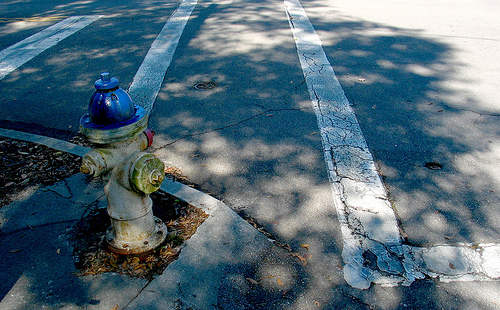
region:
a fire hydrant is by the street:
[74, 65, 171, 257]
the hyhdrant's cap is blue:
[76, 70, 147, 132]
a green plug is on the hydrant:
[129, 150, 167, 198]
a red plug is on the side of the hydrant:
[136, 126, 156, 151]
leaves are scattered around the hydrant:
[4, 131, 264, 308]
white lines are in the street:
[137, 6, 429, 284]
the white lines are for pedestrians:
[138, 7, 405, 293]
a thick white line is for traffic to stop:
[6, 7, 113, 134]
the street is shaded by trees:
[14, 8, 496, 284]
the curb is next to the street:
[7, 125, 279, 308]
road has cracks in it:
[180, 70, 320, 197]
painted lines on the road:
[81, 20, 413, 90]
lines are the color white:
[271, 50, 415, 281]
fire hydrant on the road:
[55, 75, 250, 305]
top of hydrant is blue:
[77, 40, 146, 143]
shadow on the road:
[13, 4, 472, 204]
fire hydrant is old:
[64, 57, 207, 232]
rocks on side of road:
[20, 127, 125, 251]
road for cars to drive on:
[34, 6, 470, 296]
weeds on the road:
[238, 205, 341, 300]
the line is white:
[377, 205, 390, 237]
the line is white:
[371, 220, 381, 229]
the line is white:
[376, 217, 385, 227]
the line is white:
[357, 203, 367, 242]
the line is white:
[372, 223, 384, 231]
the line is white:
[385, 201, 390, 231]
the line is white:
[363, 228, 376, 251]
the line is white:
[376, 223, 388, 254]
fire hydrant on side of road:
[68, 65, 180, 258]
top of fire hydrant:
[72, 73, 144, 144]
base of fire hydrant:
[101, 222, 168, 253]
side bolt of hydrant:
[126, 155, 165, 199]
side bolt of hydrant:
[78, 152, 99, 182]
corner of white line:
[322, 247, 402, 297]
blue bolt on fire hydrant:
[93, 70, 120, 94]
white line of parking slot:
[278, 79, 418, 286]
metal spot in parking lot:
[185, 78, 225, 100]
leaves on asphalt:
[274, 228, 311, 268]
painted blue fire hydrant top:
[75, 63, 142, 133]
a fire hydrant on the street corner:
[60, 59, 186, 286]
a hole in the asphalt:
[423, 145, 445, 176]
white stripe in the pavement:
[267, 21, 433, 306]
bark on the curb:
[17, 142, 64, 177]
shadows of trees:
[228, 10, 453, 164]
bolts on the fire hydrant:
[100, 221, 193, 260]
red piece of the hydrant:
[141, 121, 168, 154]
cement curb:
[188, 210, 307, 265]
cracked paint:
[310, 130, 405, 298]